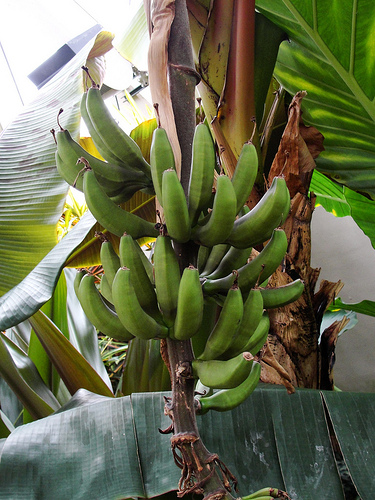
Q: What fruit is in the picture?
A: Bananas.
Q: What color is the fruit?
A: Green.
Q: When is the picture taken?
A: Daytime.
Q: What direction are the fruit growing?
A: Up.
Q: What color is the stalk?
A: Brown.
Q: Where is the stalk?
A: Behind the bananas.